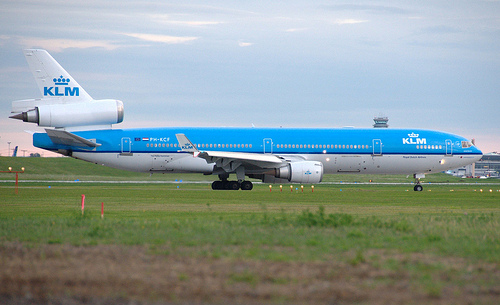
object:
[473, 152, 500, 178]
airport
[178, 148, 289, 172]
wing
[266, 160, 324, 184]
engine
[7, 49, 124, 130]
tail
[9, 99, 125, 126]
engine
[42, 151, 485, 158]
stripe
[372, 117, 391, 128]
tower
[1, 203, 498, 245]
grass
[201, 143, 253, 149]
windows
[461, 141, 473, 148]
cockpit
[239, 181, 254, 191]
wheels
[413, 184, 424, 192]
wheels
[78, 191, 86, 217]
markers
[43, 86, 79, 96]
writing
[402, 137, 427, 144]
writing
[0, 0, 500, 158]
sky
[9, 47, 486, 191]
plane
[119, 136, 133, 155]
doors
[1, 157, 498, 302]
ground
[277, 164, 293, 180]
fan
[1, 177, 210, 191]
runway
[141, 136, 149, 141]
flag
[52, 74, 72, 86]
crown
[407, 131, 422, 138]
crown